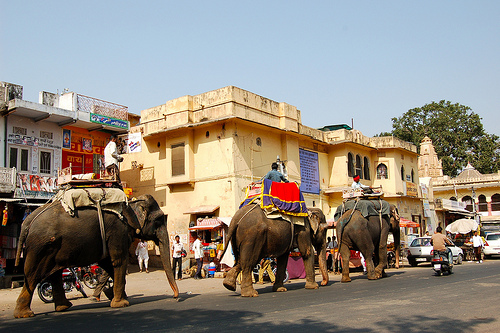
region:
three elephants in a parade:
[30, 114, 427, 286]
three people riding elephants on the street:
[73, 115, 414, 225]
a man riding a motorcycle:
[409, 212, 478, 287]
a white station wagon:
[406, 221, 474, 291]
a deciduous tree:
[393, 95, 489, 188]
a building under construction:
[12, 70, 119, 183]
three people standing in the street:
[127, 228, 212, 278]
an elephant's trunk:
[146, 220, 198, 305]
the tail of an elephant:
[1, 207, 32, 263]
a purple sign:
[284, 136, 341, 202]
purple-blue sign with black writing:
[296, 146, 321, 195]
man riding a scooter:
[428, 223, 455, 277]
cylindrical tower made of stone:
[412, 134, 443, 177]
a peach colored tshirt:
[426, 230, 446, 250]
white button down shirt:
[100, 140, 120, 166]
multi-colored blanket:
[257, 177, 308, 217]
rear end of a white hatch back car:
[481, 228, 497, 254]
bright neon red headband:
[351, 172, 359, 182]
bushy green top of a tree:
[370, 96, 496, 179]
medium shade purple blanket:
[285, 254, 305, 281]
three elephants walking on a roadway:
[0, 165, 408, 325]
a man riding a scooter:
[428, 225, 462, 275]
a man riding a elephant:
[244, 154, 300, 246]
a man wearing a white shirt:
[190, 230, 207, 266]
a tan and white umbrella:
[431, 212, 486, 237]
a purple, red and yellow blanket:
[228, 145, 315, 224]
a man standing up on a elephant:
[73, 121, 140, 246]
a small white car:
[408, 222, 436, 264]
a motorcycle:
[36, 261, 97, 308]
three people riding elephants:
[33, 130, 404, 332]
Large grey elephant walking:
[14, 192, 179, 317]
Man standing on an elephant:
[101, 134, 128, 190]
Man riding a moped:
[427, 224, 457, 283]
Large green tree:
[393, 105, 498, 167]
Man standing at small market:
[186, 225, 214, 278]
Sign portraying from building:
[296, 147, 323, 198]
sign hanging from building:
[404, 180, 419, 197]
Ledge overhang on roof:
[5, 83, 132, 128]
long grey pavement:
[305, 290, 476, 328]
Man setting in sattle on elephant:
[345, 176, 390, 203]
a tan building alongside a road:
[126, 100, 424, 283]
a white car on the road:
[405, 233, 462, 270]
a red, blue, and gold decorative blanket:
[257, 177, 314, 219]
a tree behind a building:
[375, 95, 496, 184]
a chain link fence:
[473, 185, 498, 250]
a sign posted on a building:
[290, 144, 326, 200]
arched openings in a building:
[449, 193, 498, 211]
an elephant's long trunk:
[153, 235, 183, 305]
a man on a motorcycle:
[425, 223, 461, 279]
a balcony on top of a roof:
[50, 91, 127, 126]